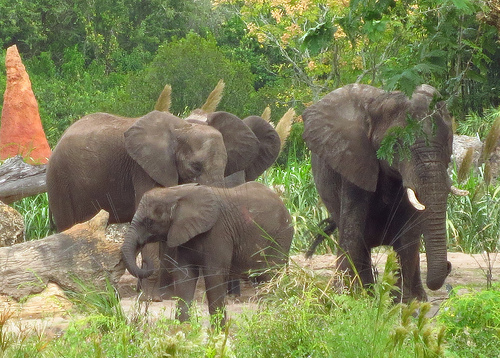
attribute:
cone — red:
[2, 42, 53, 165]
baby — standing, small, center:
[122, 181, 294, 321]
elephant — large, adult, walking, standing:
[302, 83, 453, 307]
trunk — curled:
[415, 208, 452, 289]